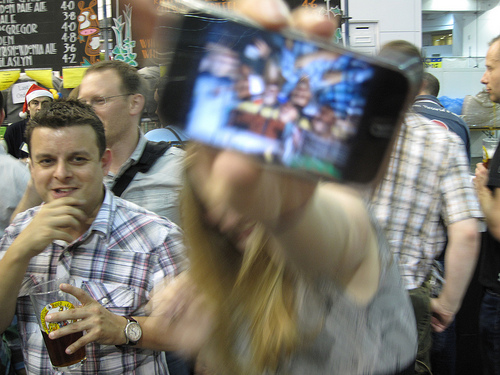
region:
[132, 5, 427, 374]
a girl holds her phone up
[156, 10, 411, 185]
screen of a phone is moving and blurry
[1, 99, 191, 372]
a guy in a plaid shirt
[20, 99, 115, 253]
guy is touching his chin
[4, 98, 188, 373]
guy is holding a beer glass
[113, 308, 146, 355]
watch on a left wrist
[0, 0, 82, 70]
a board shows alcohol content of beers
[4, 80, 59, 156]
a man is wearing a santa hat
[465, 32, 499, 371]
guy is holding a beer glass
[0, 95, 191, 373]
guy has short dark hair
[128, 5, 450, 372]
person holding up cell phone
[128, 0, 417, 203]
cell phone powered on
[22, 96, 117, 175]
man with brown shirt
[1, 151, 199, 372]
man wearing plaid shirt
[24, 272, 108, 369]
man holding drinking glass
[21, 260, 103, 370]
glass has yellow decal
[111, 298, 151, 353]
man wearing wrist watch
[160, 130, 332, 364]
person with blonde hair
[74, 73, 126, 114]
man wearing eyeglasses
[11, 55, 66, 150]
man wearing santa clause hat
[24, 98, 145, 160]
Person has short hair.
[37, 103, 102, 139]
Person has brown hair.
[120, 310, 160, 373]
Person wearing watch on wrist.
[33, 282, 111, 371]
Person holding glass in hand.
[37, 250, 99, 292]
Person wearing button down shirt.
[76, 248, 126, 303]
Person wearing plaid shirt.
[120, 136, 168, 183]
Black strap around man's shoulder.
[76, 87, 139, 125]
Glasses on person's face.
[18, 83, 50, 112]
Person wearing red and white hat.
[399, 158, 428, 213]
Person wearing plaid shirt.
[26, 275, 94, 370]
Beer in man's hand.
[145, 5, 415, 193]
Selfie being taken by a woman.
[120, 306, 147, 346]
Man wearing a watch.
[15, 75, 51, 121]
Man with a Santa hat on.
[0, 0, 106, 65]
Chalk board with numbers on it.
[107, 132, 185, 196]
Man with black strap.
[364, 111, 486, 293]
Back of man with a plaid shirt.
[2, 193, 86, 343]
Man holding up hand by his chin.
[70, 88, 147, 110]
Man with glasses on his head.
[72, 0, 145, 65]
Christmas decorations in the back.